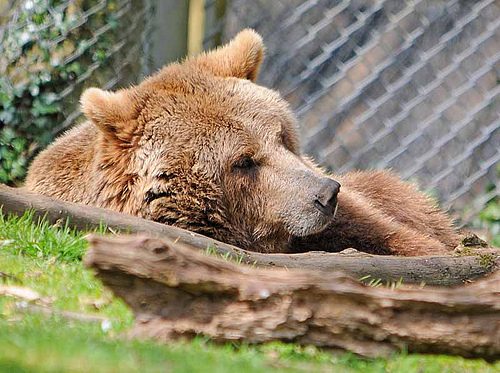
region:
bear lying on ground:
[24, 30, 486, 275]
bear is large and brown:
[12, 25, 476, 266]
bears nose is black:
[306, 167, 343, 212]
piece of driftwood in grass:
[74, 230, 498, 366]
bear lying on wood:
[1, 177, 498, 294]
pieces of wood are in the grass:
[3, 205, 498, 371]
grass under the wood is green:
[1, 205, 498, 372]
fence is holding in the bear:
[185, 1, 497, 256]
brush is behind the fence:
[1, 2, 158, 197]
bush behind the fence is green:
[1, 2, 168, 185]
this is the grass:
[25, 324, 79, 359]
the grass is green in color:
[26, 318, 75, 350]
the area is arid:
[11, 286, 93, 323]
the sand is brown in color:
[17, 287, 80, 333]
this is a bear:
[22, 26, 472, 236]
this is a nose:
[319, 180, 344, 207]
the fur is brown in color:
[157, 85, 218, 120]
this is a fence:
[348, 50, 448, 97]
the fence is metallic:
[358, 19, 451, 95]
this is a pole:
[176, 8, 196, 59]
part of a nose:
[303, 162, 343, 213]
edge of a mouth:
[298, 210, 322, 235]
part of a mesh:
[428, 132, 460, 157]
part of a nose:
[313, 176, 351, 208]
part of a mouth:
[305, 199, 322, 216]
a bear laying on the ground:
[0, 53, 450, 354]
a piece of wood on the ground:
[0, 235, 475, 355]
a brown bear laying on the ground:
[0, 76, 475, 312]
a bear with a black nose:
[304, 163, 358, 230]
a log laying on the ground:
[74, 259, 491, 371]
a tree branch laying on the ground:
[9, 193, 482, 280]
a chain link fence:
[320, 8, 473, 135]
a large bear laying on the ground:
[10, 32, 460, 262]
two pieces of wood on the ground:
[3, 202, 492, 358]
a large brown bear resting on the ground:
[7, 29, 456, 322]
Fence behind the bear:
[6, 4, 491, 212]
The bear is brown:
[24, 28, 468, 260]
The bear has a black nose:
[310, 174, 345, 216]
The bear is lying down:
[28, 28, 466, 265]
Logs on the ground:
[6, 171, 482, 361]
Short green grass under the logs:
[5, 209, 471, 368]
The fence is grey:
[3, 2, 493, 199]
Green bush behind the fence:
[4, 4, 136, 192]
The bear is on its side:
[26, 28, 468, 268]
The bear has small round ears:
[76, 19, 263, 144]